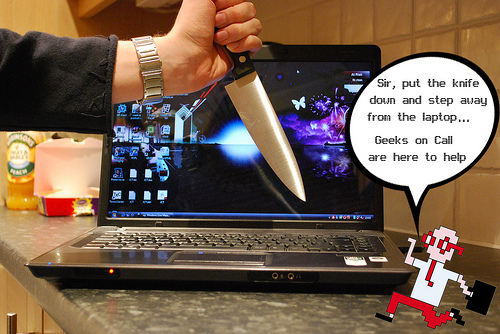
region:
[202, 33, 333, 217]
this is a kitchen knife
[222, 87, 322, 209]
the blade is silver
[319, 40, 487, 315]
this ius a cartoon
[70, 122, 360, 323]
this is a laptop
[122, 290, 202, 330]
the countertop is granite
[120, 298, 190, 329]
the countertop is speckled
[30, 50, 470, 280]
this is a photoshopped picture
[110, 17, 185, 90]
the person has on a watch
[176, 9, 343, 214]
hand holding a knife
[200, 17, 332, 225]
knife pointing down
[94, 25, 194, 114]
watchband on someone's wrist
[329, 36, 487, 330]
cartoon in the picture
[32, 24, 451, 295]
laptop on the counter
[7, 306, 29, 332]
handle on the cabinet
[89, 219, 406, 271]
keyboard on the laptop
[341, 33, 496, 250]
cartoon quote coming from man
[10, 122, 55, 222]
bottle on the counter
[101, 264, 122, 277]
power light on the computer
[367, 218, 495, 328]
a cartoon character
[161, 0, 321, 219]
a hand holding a knife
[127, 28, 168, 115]
a silver watch band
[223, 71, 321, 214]
the blade of a knife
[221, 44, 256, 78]
the handle of a knife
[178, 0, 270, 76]
a hand gripping a knife handle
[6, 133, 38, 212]
a bottle of peach juice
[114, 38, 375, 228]
the LCD screen of a laptop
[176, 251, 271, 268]
the touch-pad of a laptop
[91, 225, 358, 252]
the keyboard of a laptop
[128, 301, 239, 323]
gray stone color on the table top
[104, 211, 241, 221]
blue line across the screen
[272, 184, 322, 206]
silver tip on knife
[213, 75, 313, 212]
long silver knife blade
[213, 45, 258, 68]
small silver bolt on the knife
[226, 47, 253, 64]
black blade on the knife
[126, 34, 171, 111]
silver band on the watch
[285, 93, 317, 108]
small butterfly on the screen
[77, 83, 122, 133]
edge of black jacket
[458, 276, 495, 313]
small black suit case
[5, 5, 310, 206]
a person holding a knife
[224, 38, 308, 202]
a knife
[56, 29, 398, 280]
a laptop on the counter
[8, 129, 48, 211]
a bottle on the counter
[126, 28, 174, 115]
a watch on the person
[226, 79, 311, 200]
the blade of the knife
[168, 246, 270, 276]
the mouse pad of the computer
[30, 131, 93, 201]
a box on the counter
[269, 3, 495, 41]
tile on the wall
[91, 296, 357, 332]
the black counter top